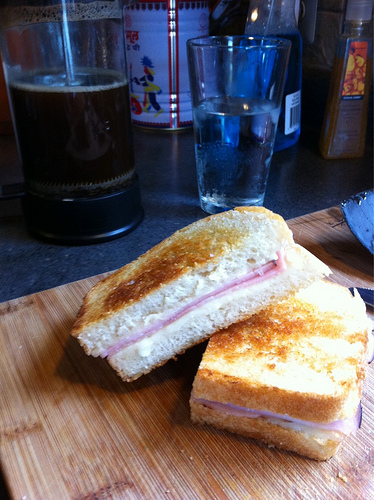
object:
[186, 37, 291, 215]
glass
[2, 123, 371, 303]
table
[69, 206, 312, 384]
sandwich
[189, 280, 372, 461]
sandwich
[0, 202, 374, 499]
board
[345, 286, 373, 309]
knife